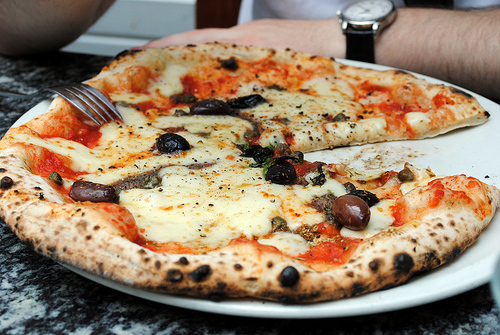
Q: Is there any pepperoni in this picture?
A: No, there is no pepperoni.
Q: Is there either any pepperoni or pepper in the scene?
A: No, there are no pepperoni or peppers.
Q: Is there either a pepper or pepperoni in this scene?
A: No, there are no pepperoni or peppers.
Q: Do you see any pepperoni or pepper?
A: No, there are no pepperoni or peppers.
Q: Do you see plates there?
A: Yes, there is a plate.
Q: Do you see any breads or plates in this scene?
A: Yes, there is a plate.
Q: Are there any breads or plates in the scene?
A: Yes, there is a plate.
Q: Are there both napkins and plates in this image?
A: No, there is a plate but no napkins.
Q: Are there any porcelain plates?
A: Yes, there is a porcelain plate.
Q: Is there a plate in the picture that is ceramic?
A: Yes, there is a plate that is ceramic.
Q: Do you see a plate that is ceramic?
A: Yes, there is a plate that is ceramic.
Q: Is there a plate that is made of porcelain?
A: Yes, there is a plate that is made of porcelain.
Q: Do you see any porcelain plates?
A: Yes, there is a plate that is made of porcelain.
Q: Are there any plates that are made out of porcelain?
A: Yes, there is a plate that is made of porcelain.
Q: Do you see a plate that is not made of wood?
A: Yes, there is a plate that is made of porcelain.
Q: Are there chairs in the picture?
A: No, there are no chairs.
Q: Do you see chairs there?
A: No, there are no chairs.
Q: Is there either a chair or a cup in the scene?
A: No, there are no chairs or cups.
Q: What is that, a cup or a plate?
A: That is a plate.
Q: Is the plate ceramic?
A: Yes, the plate is ceramic.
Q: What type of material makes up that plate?
A: The plate is made of porcelain.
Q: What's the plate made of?
A: The plate is made of porcelain.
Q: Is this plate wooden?
A: No, the plate is ceramic.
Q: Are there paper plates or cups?
A: No, there is a plate but it is ceramic.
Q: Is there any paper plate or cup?
A: No, there is a plate but it is ceramic.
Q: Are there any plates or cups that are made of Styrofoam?
A: No, there is a plate but it is made of porcelain.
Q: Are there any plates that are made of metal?
A: No, there is a plate but it is made of porcelain.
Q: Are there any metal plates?
A: No, there is a plate but it is made of porcelain.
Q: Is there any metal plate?
A: No, there is a plate but it is made of porcelain.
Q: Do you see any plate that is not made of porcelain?
A: No, there is a plate but it is made of porcelain.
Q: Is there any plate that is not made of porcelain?
A: No, there is a plate but it is made of porcelain.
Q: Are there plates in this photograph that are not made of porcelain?
A: No, there is a plate but it is made of porcelain.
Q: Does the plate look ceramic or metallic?
A: The plate is ceramic.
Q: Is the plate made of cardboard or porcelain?
A: The plate is made of porcelain.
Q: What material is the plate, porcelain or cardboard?
A: The plate is made of porcelain.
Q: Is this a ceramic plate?
A: Yes, this is a ceramic plate.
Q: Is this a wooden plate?
A: No, this is a ceramic plate.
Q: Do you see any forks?
A: Yes, there is a fork.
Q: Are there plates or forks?
A: Yes, there is a fork.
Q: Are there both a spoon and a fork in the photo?
A: No, there is a fork but no spoons.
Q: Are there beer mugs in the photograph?
A: No, there are no beer mugs.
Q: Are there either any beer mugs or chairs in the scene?
A: No, there are no beer mugs or chairs.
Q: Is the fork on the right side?
A: No, the fork is on the left of the image.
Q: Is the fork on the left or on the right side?
A: The fork is on the left of the image.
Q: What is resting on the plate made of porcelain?
A: The fork is resting on the plate.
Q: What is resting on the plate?
A: The fork is resting on the plate.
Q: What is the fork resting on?
A: The fork is resting on the plate.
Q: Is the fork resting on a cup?
A: No, the fork is resting on a plate.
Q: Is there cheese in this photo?
A: Yes, there is cheese.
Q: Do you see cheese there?
A: Yes, there is cheese.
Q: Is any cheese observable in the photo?
A: Yes, there is cheese.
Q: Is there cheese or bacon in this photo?
A: Yes, there is cheese.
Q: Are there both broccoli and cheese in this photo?
A: No, there is cheese but no broccoli.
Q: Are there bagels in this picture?
A: No, there are no bagels.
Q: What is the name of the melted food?
A: The food is cheese.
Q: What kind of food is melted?
A: The food is cheese.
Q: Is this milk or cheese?
A: This is cheese.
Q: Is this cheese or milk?
A: This is cheese.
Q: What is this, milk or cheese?
A: This is cheese.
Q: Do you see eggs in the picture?
A: No, there are no eggs.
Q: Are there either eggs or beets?
A: No, there are no eggs or beets.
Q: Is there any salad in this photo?
A: No, there is no salad.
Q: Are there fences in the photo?
A: No, there are no fences.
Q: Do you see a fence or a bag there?
A: No, there are no fences or bags.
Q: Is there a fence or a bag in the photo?
A: No, there are no fences or bags.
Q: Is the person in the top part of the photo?
A: Yes, the person is in the top of the image.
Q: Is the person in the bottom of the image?
A: No, the person is in the top of the image.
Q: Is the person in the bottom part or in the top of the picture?
A: The person is in the top of the image.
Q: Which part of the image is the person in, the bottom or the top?
A: The person is in the top of the image.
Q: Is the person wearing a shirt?
A: Yes, the person is wearing a shirt.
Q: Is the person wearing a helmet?
A: No, the person is wearing a shirt.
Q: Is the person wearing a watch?
A: Yes, the person is wearing a watch.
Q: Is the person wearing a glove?
A: No, the person is wearing a watch.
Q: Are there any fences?
A: No, there are no fences.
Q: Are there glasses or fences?
A: No, there are no fences or glasses.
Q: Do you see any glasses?
A: No, there are no glasses.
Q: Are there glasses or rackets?
A: No, there are no glasses or rackets.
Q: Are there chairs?
A: No, there are no chairs.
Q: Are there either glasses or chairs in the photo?
A: No, there are no chairs or glasses.